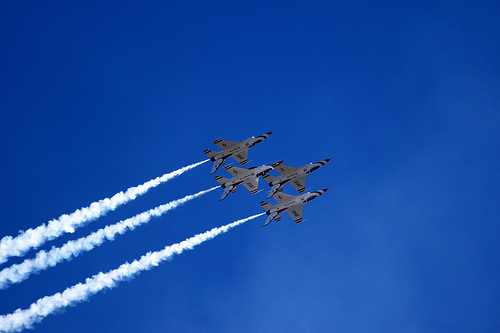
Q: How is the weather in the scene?
A: It is cloudless.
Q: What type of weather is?
A: It is cloudless.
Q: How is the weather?
A: It is cloudless.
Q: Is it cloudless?
A: Yes, it is cloudless.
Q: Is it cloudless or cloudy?
A: It is cloudless.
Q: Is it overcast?
A: No, it is cloudless.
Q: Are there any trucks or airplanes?
A: Yes, there is an airplane.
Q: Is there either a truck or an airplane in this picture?
A: Yes, there is an airplane.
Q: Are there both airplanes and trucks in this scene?
A: No, there is an airplane but no trucks.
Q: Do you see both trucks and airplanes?
A: No, there is an airplane but no trucks.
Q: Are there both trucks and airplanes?
A: No, there is an airplane but no trucks.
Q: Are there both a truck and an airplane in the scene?
A: No, there is an airplane but no trucks.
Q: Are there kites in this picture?
A: No, there are no kites.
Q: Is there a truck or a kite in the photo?
A: No, there are no kites or trucks.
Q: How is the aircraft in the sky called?
A: The aircraft is an airplane.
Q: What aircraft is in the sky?
A: The aircraft is an airplane.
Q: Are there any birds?
A: No, there are no birds.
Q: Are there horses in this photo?
A: No, there are no horses.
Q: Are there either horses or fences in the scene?
A: No, there are no horses or fences.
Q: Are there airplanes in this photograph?
A: Yes, there is an airplane.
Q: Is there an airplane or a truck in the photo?
A: Yes, there is an airplane.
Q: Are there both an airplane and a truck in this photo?
A: No, there is an airplane but no trucks.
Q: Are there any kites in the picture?
A: No, there are no kites.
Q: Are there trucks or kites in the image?
A: No, there are no kites or trucks.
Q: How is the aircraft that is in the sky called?
A: The aircraft is an airplane.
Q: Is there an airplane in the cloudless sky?
A: Yes, there is an airplane in the sky.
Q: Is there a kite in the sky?
A: No, there is an airplane in the sky.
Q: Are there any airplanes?
A: Yes, there is an airplane.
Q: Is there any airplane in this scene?
A: Yes, there is an airplane.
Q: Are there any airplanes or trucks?
A: Yes, there is an airplane.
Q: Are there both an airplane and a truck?
A: No, there is an airplane but no trucks.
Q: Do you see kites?
A: No, there are no kites.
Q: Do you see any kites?
A: No, there are no kites.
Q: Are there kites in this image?
A: No, there are no kites.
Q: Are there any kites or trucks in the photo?
A: No, there are no kites or trucks.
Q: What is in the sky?
A: The plane is in the sky.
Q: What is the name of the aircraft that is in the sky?
A: The aircraft is an airplane.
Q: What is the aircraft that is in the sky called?
A: The aircraft is an airplane.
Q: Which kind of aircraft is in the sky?
A: The aircraft is an airplane.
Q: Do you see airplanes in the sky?
A: Yes, there is an airplane in the sky.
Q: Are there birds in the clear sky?
A: No, there is an airplane in the sky.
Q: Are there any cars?
A: No, there are no cars.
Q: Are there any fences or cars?
A: No, there are no cars or fences.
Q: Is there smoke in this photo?
A: Yes, there is smoke.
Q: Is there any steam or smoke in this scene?
A: Yes, there is smoke.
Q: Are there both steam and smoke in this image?
A: No, there is smoke but no steam.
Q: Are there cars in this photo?
A: No, there are no cars.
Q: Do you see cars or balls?
A: No, there are no cars or balls.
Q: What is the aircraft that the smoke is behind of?
A: The aircraft is an airplane.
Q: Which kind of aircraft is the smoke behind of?
A: The smoke is behind the plane.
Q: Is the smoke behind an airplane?
A: Yes, the smoke is behind an airplane.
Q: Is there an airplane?
A: Yes, there is an airplane.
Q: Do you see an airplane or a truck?
A: Yes, there is an airplane.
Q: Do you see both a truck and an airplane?
A: No, there is an airplane but no trucks.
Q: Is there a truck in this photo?
A: No, there are no trucks.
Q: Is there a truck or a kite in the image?
A: No, there are no trucks or kites.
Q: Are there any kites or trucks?
A: No, there are no trucks or kites.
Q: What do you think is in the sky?
A: The plane is in the sky.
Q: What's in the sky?
A: The plane is in the sky.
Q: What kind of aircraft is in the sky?
A: The aircraft is an airplane.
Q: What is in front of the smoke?
A: The plane is in front of the smoke.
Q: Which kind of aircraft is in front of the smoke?
A: The aircraft is an airplane.